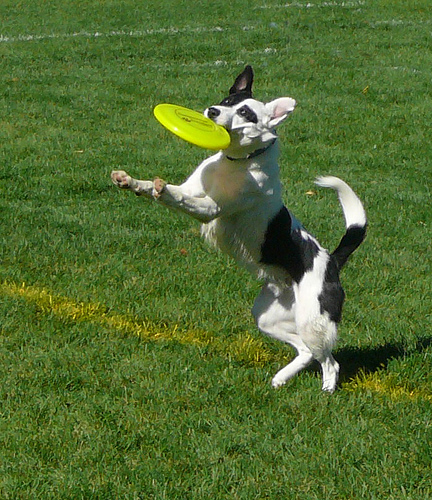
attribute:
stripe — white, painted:
[26, 18, 217, 50]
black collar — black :
[217, 136, 289, 165]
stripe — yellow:
[0, 261, 429, 405]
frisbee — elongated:
[107, 69, 245, 170]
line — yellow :
[0, 262, 430, 428]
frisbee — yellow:
[155, 105, 234, 149]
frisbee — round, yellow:
[153, 103, 230, 149]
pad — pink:
[96, 166, 172, 198]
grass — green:
[28, 340, 246, 462]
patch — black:
[229, 101, 263, 130]